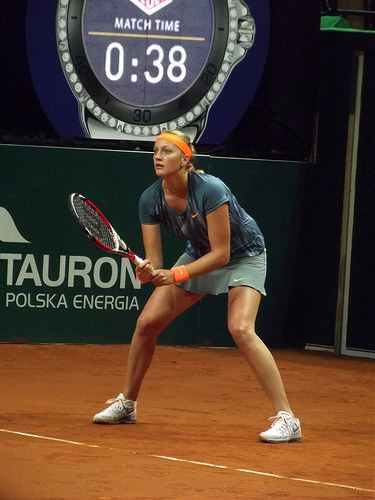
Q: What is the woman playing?
A: Tennis.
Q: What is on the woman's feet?
A: Sneakers.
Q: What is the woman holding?
A: Tennis racket.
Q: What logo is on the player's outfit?
A: Nike.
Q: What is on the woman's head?
A: Orange headband.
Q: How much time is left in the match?
A: 38 seconds.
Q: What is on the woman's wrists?
A: Orange sweatbands.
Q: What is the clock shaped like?
A: A watch.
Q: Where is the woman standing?
A: Tennis court.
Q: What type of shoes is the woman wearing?
A: Tennis shoes.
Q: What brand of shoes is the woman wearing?
A: Nike.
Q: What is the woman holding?
A: Tennis Racket.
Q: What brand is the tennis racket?
A: Wilson.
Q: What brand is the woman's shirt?
A: Nike.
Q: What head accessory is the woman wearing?
A: A headband.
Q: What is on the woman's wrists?
A: Wristbands.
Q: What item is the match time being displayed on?
A: A watch.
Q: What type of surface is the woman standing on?
A: Clay.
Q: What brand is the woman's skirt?
A: Nike.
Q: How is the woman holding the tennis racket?
A: Two handed.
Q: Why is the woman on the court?
A: To play tennis.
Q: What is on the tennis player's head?
A: An orange sweatband.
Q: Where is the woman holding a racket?
A: Tennis court.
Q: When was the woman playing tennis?
A: Evening time.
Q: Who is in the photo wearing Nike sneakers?
A: Professional tennis player.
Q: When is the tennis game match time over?
A: 0:38 seconds.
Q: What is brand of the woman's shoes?
A: Nike.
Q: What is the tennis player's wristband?
A: Orange.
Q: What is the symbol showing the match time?
A: Face of wristwatch.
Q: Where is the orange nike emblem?
A: Players shirt.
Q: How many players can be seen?
A: One.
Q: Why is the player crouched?
A: Preparing to hit.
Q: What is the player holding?
A: Racket.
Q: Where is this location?
A: Tennis court.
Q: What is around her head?
A: Headband.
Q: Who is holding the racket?
A: Tennis player.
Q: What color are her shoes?
A: White.